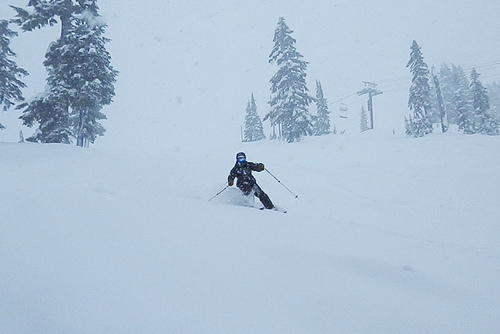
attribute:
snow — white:
[6, 211, 493, 325]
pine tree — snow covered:
[244, 91, 264, 140]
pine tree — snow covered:
[269, 16, 316, 138]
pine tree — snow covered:
[243, 99, 253, 141]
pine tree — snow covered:
[404, 37, 435, 132]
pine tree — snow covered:
[466, 64, 493, 135]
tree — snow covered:
[32, 9, 134, 142]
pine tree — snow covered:
[261, 12, 316, 142]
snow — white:
[3, 215, 499, 332]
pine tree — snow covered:
[14, 4, 121, 174]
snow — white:
[81, 221, 381, 283]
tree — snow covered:
[447, 62, 478, 136]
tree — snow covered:
[262, 15, 319, 142]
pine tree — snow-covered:
[358, 102, 372, 133]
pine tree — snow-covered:
[308, 78, 333, 136]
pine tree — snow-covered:
[259, 15, 321, 143]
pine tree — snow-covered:
[241, 92, 268, 143]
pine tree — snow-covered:
[403, 37, 433, 137]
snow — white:
[269, 19, 311, 139]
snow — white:
[241, 110, 261, 140]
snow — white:
[267, 10, 497, 130]